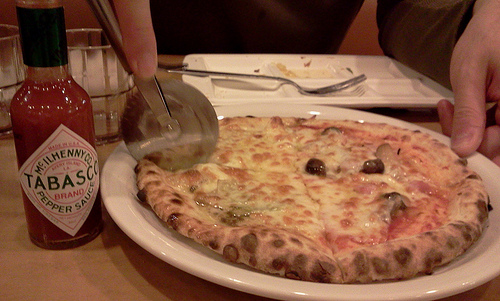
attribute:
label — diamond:
[15, 119, 101, 239]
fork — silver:
[161, 53, 370, 100]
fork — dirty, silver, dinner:
[167, 57, 370, 100]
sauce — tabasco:
[5, 1, 111, 246]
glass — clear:
[83, 46, 150, 129]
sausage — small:
[302, 153, 329, 183]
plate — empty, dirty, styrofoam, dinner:
[170, 47, 460, 121]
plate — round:
[108, 99, 498, 284]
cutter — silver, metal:
[89, 60, 229, 175]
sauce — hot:
[9, 7, 104, 249]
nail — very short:
[449, 127, 473, 148]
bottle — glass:
[11, 0, 103, 249]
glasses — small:
[61, 30, 138, 126]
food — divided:
[119, 103, 497, 282]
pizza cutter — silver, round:
[99, 4, 230, 179]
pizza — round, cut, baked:
[160, 94, 492, 299]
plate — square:
[177, 50, 482, 109]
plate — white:
[176, 50, 464, 112]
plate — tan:
[99, 96, 480, 299]